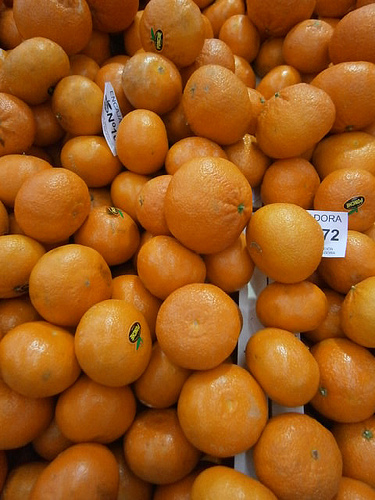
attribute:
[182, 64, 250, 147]
orange — rough-skinned, textured, unpeeled, present, for sale, round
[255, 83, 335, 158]
orange — rough-skinned, textured, unpeeled, present, for sale, round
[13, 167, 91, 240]
orange — rough-skinned, textured, unpeeled, present, for sale, round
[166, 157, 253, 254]
orange — rough-skinned, textured, unpeeled, present, for sale, round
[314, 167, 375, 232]
orange — rough-skinned, textured, unpeeled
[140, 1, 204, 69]
orange — unpeeled, present, for sale, round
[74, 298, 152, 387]
orange — for sale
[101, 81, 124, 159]
price tag — white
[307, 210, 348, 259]
price tag — white